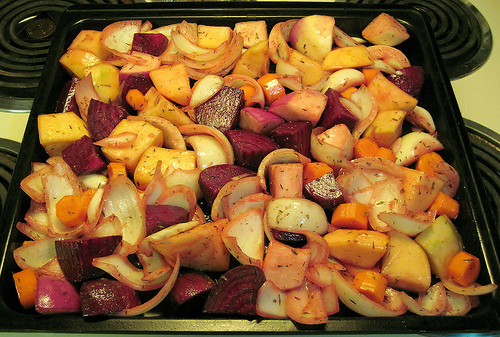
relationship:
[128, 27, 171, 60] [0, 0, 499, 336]
beet cooking on pan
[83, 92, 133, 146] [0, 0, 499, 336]
beet cooking on pan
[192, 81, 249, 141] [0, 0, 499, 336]
beet cooking on pan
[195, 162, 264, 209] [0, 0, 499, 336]
beet cooking on pan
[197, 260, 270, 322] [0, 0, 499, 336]
beet cooking on pan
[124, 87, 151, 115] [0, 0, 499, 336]
carrot cooking in pan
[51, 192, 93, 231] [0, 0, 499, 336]
carrot cooking in pan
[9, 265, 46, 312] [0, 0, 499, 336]
carrot cooking in pan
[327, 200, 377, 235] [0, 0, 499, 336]
carrot cooking in pan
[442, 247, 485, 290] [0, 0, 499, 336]
carrot cooking in pan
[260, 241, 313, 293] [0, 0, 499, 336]
onion steaming in pan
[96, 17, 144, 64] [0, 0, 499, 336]
onion steaming in pan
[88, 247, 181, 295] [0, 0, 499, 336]
onion steaming in pan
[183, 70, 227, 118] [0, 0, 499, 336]
onion steaming in pan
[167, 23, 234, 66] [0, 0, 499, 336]
onion steaming in pan